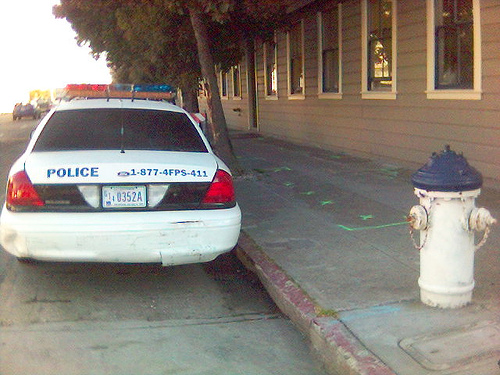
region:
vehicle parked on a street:
[0, 71, 250, 279]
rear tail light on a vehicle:
[199, 165, 242, 213]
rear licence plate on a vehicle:
[96, 179, 151, 216]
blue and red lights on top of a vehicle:
[58, 78, 185, 105]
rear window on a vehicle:
[28, 103, 214, 158]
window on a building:
[353, 0, 403, 107]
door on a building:
[242, 29, 264, 136]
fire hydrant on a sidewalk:
[397, 134, 498, 312]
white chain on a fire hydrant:
[470, 223, 492, 257]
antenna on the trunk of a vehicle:
[114, 94, 129, 160]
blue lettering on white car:
[42, 161, 100, 178]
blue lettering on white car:
[130, 164, 209, 179]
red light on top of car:
[63, 79, 106, 101]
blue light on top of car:
[132, 78, 170, 98]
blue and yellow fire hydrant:
[412, 142, 492, 304]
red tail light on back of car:
[203, 168, 238, 207]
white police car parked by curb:
[3, 76, 241, 288]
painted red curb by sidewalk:
[238, 235, 384, 373]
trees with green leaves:
[53, 1, 308, 83]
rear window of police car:
[45, 105, 212, 160]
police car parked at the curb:
[3, 80, 245, 272]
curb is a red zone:
[229, 218, 399, 373]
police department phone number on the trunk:
[127, 163, 212, 180]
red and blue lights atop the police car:
[59, 80, 183, 101]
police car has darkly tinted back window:
[29, 105, 211, 155]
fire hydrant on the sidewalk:
[404, 140, 496, 310]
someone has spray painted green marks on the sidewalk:
[245, 158, 417, 233]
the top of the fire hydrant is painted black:
[408, 138, 485, 195]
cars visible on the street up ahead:
[10, 95, 56, 121]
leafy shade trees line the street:
[50, 2, 255, 177]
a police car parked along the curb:
[34, 77, 274, 299]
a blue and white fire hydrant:
[381, 133, 496, 330]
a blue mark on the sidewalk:
[301, 288, 399, 338]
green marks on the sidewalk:
[268, 162, 404, 271]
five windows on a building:
[256, 0, 497, 140]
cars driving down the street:
[13, 78, 56, 130]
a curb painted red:
[241, 230, 359, 368]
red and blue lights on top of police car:
[56, 73, 189, 110]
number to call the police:
[128, 160, 216, 183]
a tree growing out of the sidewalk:
[142, 20, 293, 202]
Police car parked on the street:
[21, 71, 236, 269]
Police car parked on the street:
[22, 75, 235, 276]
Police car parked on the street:
[43, 163, 113, 205]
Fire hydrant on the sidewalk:
[407, 125, 492, 317]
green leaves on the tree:
[121, 38, 153, 71]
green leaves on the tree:
[170, 49, 195, 76]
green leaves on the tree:
[217, 17, 241, 54]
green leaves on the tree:
[72, 14, 107, 53]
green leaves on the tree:
[248, 8, 274, 30]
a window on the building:
[423, 6, 489, 112]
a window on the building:
[357, 3, 397, 90]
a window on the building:
[320, 8, 346, 78]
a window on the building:
[282, 34, 317, 90]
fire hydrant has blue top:
[396, 135, 486, 193]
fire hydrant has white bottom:
[404, 178, 482, 310]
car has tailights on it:
[205, 168, 240, 212]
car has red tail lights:
[203, 159, 240, 214]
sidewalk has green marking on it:
[271, 142, 387, 262]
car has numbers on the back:
[123, 160, 224, 189]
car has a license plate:
[102, 186, 156, 207]